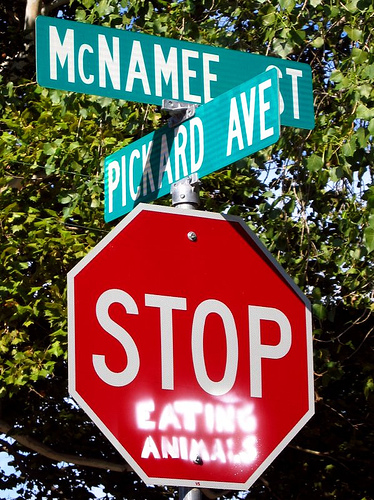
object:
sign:
[62, 197, 316, 494]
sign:
[99, 67, 285, 228]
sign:
[33, 9, 319, 135]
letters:
[243, 296, 294, 401]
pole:
[161, 96, 202, 499]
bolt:
[185, 225, 200, 245]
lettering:
[105, 78, 275, 213]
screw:
[191, 453, 204, 467]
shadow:
[132, 99, 178, 206]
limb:
[3, 429, 123, 475]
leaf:
[305, 150, 327, 186]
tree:
[4, 1, 373, 499]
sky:
[226, 7, 374, 218]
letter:
[90, 281, 144, 391]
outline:
[63, 202, 316, 494]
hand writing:
[133, 392, 257, 435]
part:
[170, 187, 197, 205]